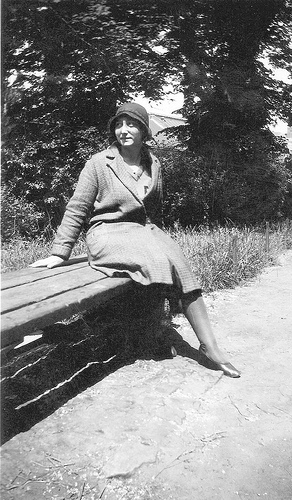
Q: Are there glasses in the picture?
A: No, there are no glasses.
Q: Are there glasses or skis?
A: No, there are no glasses or skis.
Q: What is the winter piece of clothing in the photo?
A: The clothing item is a jacket.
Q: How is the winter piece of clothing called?
A: The clothing item is a jacket.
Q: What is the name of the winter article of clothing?
A: The clothing item is a jacket.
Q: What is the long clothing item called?
A: The clothing item is a jacket.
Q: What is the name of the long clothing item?
A: The clothing item is a jacket.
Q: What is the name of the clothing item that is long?
A: The clothing item is a jacket.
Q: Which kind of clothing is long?
A: The clothing is a jacket.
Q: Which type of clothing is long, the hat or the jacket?
A: The jacket is long.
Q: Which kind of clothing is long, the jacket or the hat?
A: The jacket is long.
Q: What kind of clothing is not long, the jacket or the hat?
A: The hat is not long.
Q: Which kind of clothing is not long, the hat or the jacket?
A: The hat is not long.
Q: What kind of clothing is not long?
A: The clothing is a hat.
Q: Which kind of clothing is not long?
A: The clothing is a hat.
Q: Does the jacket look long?
A: Yes, the jacket is long.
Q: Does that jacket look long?
A: Yes, the jacket is long.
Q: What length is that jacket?
A: The jacket is long.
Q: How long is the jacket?
A: The jacket is long.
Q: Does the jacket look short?
A: No, the jacket is long.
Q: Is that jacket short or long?
A: The jacket is long.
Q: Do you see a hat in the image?
A: Yes, there is a hat.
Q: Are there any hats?
A: Yes, there is a hat.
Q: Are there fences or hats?
A: Yes, there is a hat.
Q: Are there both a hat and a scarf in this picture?
A: No, there is a hat but no scarves.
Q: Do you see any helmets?
A: No, there are no helmets.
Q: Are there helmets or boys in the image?
A: No, there are no helmets or boys.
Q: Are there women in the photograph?
A: Yes, there is a woman.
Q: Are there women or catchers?
A: Yes, there is a woman.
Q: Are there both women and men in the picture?
A: No, there is a woman but no men.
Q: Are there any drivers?
A: No, there are no drivers.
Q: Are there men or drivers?
A: No, there are no drivers or men.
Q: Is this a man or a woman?
A: This is a woman.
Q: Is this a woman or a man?
A: This is a woman.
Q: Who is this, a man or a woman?
A: This is a woman.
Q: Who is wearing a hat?
A: The woman is wearing a hat.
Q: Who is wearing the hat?
A: The woman is wearing a hat.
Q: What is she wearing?
A: The woman is wearing a hat.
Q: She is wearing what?
A: The woman is wearing a hat.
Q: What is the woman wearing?
A: The woman is wearing a hat.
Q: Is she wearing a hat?
A: Yes, the woman is wearing a hat.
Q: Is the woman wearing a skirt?
A: No, the woman is wearing a hat.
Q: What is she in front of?
A: The woman is in front of the trees.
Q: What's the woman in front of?
A: The woman is in front of the trees.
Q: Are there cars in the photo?
A: No, there are no cars.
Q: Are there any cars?
A: No, there are no cars.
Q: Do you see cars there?
A: No, there are no cars.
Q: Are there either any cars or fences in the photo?
A: No, there are no cars or fences.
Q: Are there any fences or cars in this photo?
A: No, there are no cars or fences.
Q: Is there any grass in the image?
A: Yes, there is grass.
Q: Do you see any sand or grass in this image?
A: Yes, there is grass.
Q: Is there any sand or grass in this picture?
A: Yes, there is grass.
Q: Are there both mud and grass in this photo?
A: No, there is grass but no mud.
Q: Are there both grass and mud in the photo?
A: No, there is grass but no mud.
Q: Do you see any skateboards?
A: No, there are no skateboards.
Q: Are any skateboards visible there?
A: No, there are no skateboards.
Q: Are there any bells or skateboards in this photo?
A: No, there are no skateboards or bells.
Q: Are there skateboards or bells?
A: No, there are no skateboards or bells.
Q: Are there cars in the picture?
A: No, there are no cars.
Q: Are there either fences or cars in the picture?
A: No, there are no cars or fences.